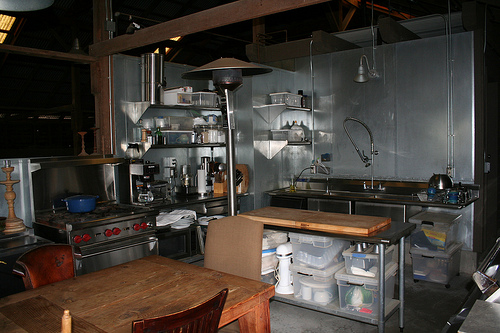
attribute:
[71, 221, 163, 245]
knobs — red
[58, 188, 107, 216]
pot — blue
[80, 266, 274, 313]
table — wooden, brown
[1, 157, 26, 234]
candle holder — wooden, wodoen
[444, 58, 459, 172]
tubes — silver